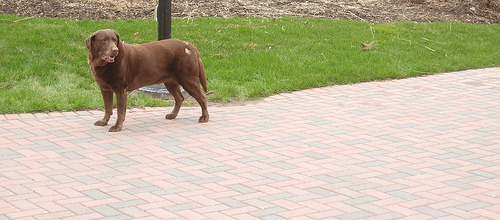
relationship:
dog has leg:
[84, 27, 210, 132] [94, 87, 113, 126]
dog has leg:
[84, 27, 210, 132] [108, 85, 128, 131]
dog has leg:
[84, 27, 210, 132] [163, 79, 184, 121]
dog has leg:
[84, 27, 210, 132] [178, 76, 209, 123]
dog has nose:
[84, 27, 210, 132] [112, 47, 119, 54]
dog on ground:
[84, 27, 210, 132] [1, 66, 499, 219]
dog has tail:
[84, 27, 210, 132] [198, 56, 209, 93]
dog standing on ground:
[84, 27, 210, 132] [1, 66, 499, 219]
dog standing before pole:
[84, 27, 210, 132] [157, 1, 171, 42]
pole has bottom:
[157, 1, 171, 42] [136, 82, 192, 101]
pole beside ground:
[157, 1, 171, 42] [1, 66, 499, 219]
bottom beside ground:
[136, 82, 192, 101] [1, 66, 499, 219]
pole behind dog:
[157, 1, 171, 42] [84, 27, 210, 132]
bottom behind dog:
[136, 82, 192, 101] [84, 27, 210, 132]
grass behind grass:
[1, 1, 498, 24] [0, 13, 498, 115]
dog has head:
[84, 27, 210, 132] [85, 29, 122, 63]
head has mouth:
[85, 29, 122, 63] [101, 53, 118, 61]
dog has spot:
[84, 27, 210, 132] [181, 40, 190, 46]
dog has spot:
[84, 27, 210, 132] [184, 46, 191, 55]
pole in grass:
[157, 1, 171, 42] [0, 13, 498, 115]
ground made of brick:
[1, 66, 499, 219] [240, 158, 276, 171]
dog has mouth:
[84, 27, 210, 132] [101, 53, 118, 61]